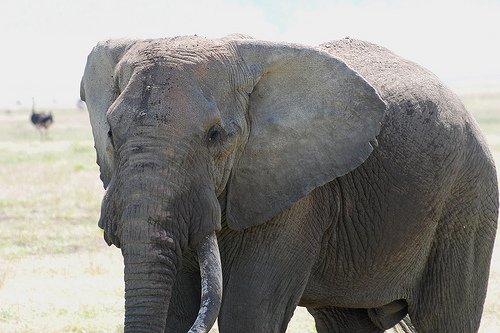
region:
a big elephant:
[63, 23, 481, 331]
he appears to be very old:
[78, 29, 498, 331]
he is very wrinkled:
[91, 15, 488, 327]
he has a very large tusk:
[186, 229, 243, 329]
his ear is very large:
[183, 26, 424, 302]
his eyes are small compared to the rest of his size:
[103, 113, 238, 148]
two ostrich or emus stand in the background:
[25, 81, 67, 146]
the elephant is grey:
[76, 28, 498, 328]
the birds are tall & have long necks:
[23, 93, 58, 148]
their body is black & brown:
[26, 99, 67, 136]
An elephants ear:
[226, 39, 387, 235]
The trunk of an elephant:
[98, 143, 205, 327]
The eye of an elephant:
[202, 120, 226, 151]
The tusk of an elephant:
[195, 228, 228, 330]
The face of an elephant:
[62, 29, 289, 275]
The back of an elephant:
[297, 25, 480, 139]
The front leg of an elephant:
[233, 230, 305, 329]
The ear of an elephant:
[83, 41, 133, 183]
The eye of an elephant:
[102, 116, 122, 155]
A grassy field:
[20, 218, 91, 318]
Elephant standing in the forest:
[73, 33, 494, 331]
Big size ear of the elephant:
[225, 38, 390, 241]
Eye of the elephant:
[199, 121, 234, 150]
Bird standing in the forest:
[25, 95, 64, 155]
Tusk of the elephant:
[188, 240, 231, 330]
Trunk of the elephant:
[118, 247, 172, 332]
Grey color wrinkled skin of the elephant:
[325, 185, 491, 272]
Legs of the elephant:
[168, 306, 473, 331]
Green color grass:
[10, 150, 90, 272]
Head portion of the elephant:
[92, 18, 300, 218]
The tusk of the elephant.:
[192, 230, 230, 330]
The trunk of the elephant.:
[115, 239, 170, 331]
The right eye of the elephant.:
[202, 117, 224, 144]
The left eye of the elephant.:
[104, 118, 123, 145]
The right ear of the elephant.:
[230, 31, 385, 229]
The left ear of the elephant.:
[81, 37, 123, 185]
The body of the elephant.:
[311, 21, 493, 298]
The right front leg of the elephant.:
[229, 225, 297, 331]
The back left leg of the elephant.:
[308, 303, 372, 331]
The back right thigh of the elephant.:
[433, 190, 494, 332]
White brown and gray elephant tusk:
[190, 232, 227, 332]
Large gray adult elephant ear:
[235, 33, 388, 233]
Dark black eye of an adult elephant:
[202, 124, 225, 147]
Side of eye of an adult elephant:
[103, 120, 119, 145]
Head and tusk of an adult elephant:
[70, 36, 260, 331]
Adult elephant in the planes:
[71, 26, 491, 331]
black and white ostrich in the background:
[23, 94, 59, 140]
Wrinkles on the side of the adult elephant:
[324, 191, 385, 264]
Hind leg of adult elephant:
[422, 139, 497, 329]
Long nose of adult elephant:
[111, 193, 183, 330]